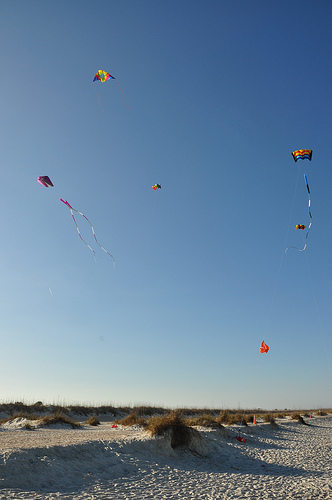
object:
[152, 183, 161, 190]
kite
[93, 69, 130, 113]
kite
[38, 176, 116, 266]
kite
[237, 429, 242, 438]
person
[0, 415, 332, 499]
riverbank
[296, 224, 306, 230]
kites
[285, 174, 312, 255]
long tail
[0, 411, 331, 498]
sand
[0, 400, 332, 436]
plant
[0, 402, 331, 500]
ground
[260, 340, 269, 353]
colorful kite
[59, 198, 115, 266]
striped tail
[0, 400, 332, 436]
grass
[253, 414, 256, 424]
cone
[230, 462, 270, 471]
prints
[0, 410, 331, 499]
beach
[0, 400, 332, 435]
bush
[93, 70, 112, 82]
rainbow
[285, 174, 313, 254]
ribbons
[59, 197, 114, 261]
ribbons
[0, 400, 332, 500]
sand dune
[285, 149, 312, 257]
kite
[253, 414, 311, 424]
caution cones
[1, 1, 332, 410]
sky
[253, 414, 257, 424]
item